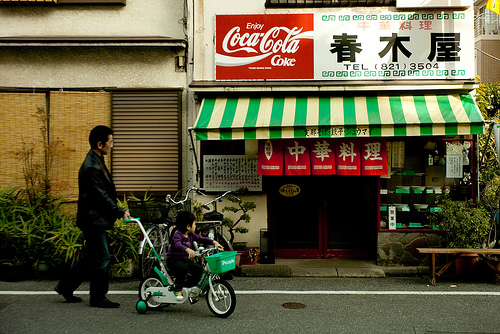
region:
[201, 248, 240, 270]
a green basket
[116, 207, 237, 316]
a small green and white bike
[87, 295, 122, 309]
a man's black shoe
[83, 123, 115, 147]
a man's short cut black hair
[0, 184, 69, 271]
a large green bush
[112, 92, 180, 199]
a window of a building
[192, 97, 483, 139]
a green and white canopy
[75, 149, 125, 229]
a man's black jacket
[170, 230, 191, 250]
the arm of a little girl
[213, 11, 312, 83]
red and white coca-cola sign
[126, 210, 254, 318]
child riding a bicycle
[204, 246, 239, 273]
green basket on the bicycle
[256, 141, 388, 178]
red and white banners hanging from awning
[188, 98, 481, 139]
green and white striped awning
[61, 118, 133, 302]
man wearing black coat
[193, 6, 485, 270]
storefront along the street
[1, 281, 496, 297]
white line painted on the street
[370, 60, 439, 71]
black numbers on white background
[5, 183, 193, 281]
plants along the roadway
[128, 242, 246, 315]
a green and white bike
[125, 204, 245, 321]
a boy on a green and white bike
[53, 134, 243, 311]
a man pushing a bike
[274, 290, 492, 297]
a white line on the road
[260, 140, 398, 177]
red sign hanging down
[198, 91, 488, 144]
a green and white covering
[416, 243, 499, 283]
a brown wooden bench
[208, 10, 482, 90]
a sign on the store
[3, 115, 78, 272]
green bush by the building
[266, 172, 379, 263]
a brown door way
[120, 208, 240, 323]
green and white bicycle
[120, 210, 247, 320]
bicycle with training wheels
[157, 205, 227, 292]
child riding green and white bike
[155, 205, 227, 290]
young child with purple shirt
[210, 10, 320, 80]
coca-cola advertisement on building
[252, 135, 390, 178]
red and white banner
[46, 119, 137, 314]
adult male in leather coat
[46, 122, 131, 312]
adult male with black hair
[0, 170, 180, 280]
plants along building wall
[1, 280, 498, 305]
painted white stripe on street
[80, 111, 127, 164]
head of a person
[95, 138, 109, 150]
ear of a person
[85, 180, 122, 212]
arm of a person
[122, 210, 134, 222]
hand of a person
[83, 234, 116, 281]
leg of a person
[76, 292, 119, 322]
feet of a person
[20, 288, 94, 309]
feet of a person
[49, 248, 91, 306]
leg of a person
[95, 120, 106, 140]
hair of a person